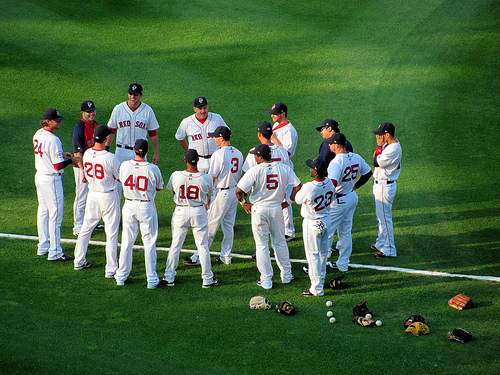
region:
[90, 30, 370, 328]
a team of baseball players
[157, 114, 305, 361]
a team of baseball players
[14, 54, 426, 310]
Players gather on field.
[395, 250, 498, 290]
White chalk on the grass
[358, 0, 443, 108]
Mow lines in the grass.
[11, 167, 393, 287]
The uniforms are white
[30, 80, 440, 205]
The group wear hats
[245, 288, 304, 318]
Baseball mitts on the ground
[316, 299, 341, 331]
A line of baseballs.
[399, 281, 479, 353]
More gloves on the ground.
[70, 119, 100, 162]
A red and blue jacket.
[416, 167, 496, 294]
The men's shadows on the ground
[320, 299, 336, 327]
three white baseballs on the ground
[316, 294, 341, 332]
three white baseballs on the ground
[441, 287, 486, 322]
Glove is on ground.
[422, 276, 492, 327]
The glove is brown.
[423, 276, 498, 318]
The glove is leather.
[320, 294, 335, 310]
The ball is round.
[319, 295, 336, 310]
The ball is white.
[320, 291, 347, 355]
Three balls on the ground.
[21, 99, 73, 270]
Man is wearing cap.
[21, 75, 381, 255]
Shirts have numbers on them.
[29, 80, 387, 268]
The numbers are red.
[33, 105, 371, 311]
Uniform shirts are white.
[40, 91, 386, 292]
baseball team near foul line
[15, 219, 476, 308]
white line on field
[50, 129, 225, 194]
players wear white shirt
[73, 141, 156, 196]
red numbers on white shirts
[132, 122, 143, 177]
players wear blue caps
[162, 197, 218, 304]
players wear white pants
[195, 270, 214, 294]
players wear dark colored shoes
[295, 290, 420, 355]
white baseballs behind players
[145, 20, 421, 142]
shadows on field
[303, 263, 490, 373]
baseball gloves behind players